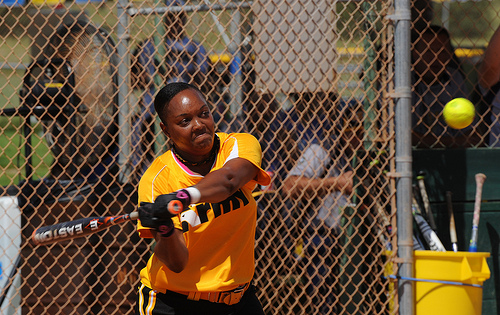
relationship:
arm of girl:
[194, 159, 258, 205] [138, 82, 261, 314]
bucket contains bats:
[383, 250, 492, 314] [380, 173, 489, 251]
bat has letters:
[32, 210, 136, 245] [33, 222, 98, 242]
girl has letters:
[138, 82, 261, 314] [181, 195, 253, 236]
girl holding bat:
[138, 82, 261, 314] [32, 210, 136, 245]